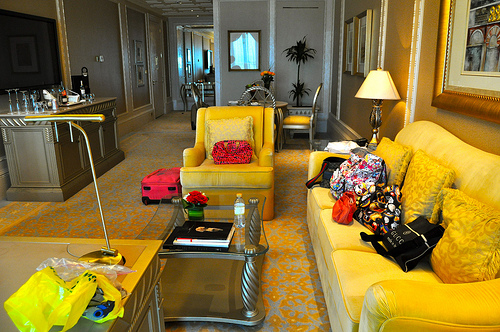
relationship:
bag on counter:
[2, 260, 129, 331] [1, 231, 165, 331]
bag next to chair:
[137, 164, 182, 208] [177, 99, 281, 223]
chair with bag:
[177, 99, 281, 223] [211, 137, 252, 168]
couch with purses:
[303, 117, 500, 331] [360, 210, 450, 274]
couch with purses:
[303, 117, 500, 331] [330, 189, 356, 226]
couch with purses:
[303, 117, 500, 331] [304, 153, 351, 195]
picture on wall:
[429, 1, 500, 128] [325, 1, 500, 236]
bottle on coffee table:
[232, 190, 246, 229] [133, 193, 272, 331]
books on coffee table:
[159, 218, 240, 255] [133, 193, 272, 331]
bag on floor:
[137, 164, 182, 208] [1, 108, 471, 331]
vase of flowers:
[262, 80, 274, 101] [259, 67, 278, 82]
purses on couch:
[360, 210, 450, 274] [303, 117, 500, 331]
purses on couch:
[330, 189, 356, 226] [303, 117, 500, 331]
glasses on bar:
[5, 88, 16, 113] [1, 89, 126, 206]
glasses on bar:
[12, 84, 23, 115] [1, 89, 126, 206]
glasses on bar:
[19, 89, 32, 116] [1, 89, 126, 206]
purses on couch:
[304, 153, 351, 195] [303, 117, 500, 331]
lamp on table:
[352, 67, 405, 158] [309, 134, 388, 162]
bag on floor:
[2, 260, 129, 331] [1, 108, 471, 331]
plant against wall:
[279, 37, 324, 144] [208, 0, 337, 141]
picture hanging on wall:
[429, 1, 500, 128] [325, 1, 500, 236]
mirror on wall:
[225, 28, 264, 77] [208, 0, 337, 141]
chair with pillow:
[177, 99, 281, 223] [202, 114, 260, 163]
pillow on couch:
[362, 136, 411, 202] [303, 117, 500, 331]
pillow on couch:
[395, 147, 457, 245] [303, 117, 500, 331]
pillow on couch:
[430, 186, 499, 288] [303, 117, 500, 331]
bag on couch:
[327, 151, 388, 205] [303, 117, 500, 331]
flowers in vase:
[259, 67, 278, 82] [262, 80, 274, 101]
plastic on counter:
[28, 247, 129, 295] [1, 231, 165, 331]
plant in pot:
[279, 37, 324, 144] [285, 102, 322, 143]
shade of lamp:
[355, 68, 400, 105] [352, 67, 405, 158]